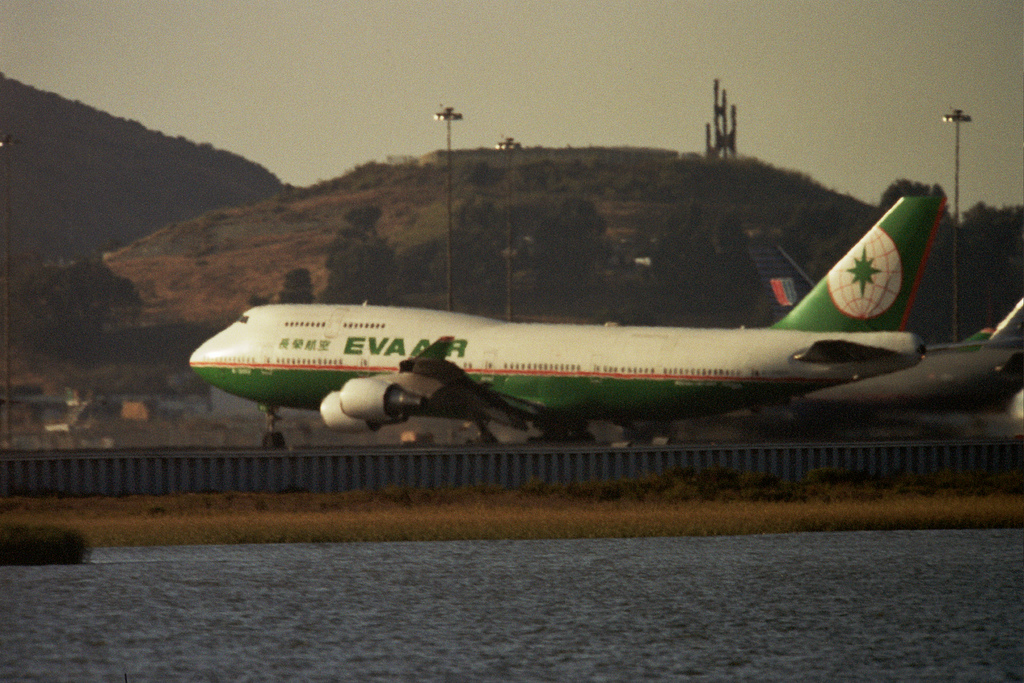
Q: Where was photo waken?
A: At the airport.